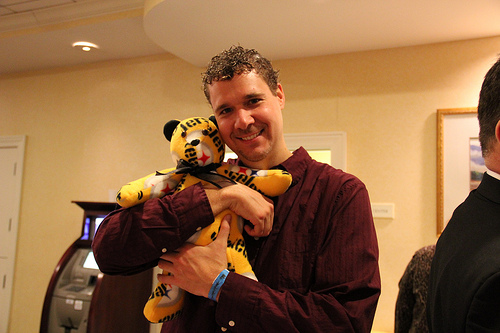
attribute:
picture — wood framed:
[427, 95, 495, 238]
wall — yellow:
[0, 37, 499, 328]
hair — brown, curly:
[189, 50, 301, 107]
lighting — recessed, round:
[71, 41, 99, 53]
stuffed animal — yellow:
[117, 115, 294, 326]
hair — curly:
[200, 44, 281, 104]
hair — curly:
[192, 41, 280, 98]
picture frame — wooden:
[435, 107, 480, 242]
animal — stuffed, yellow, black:
[115, 114, 292, 323]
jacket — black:
[423, 169, 495, 329]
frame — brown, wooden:
[434, 102, 494, 239]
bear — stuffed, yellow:
[114, 112, 291, 318]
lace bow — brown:
[152, 157, 224, 176]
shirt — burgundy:
[89, 146, 381, 331]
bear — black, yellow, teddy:
[117, 117, 299, 327]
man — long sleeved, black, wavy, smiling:
[85, 33, 389, 331]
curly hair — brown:
[200, 39, 284, 91]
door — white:
[1, 134, 28, 331]